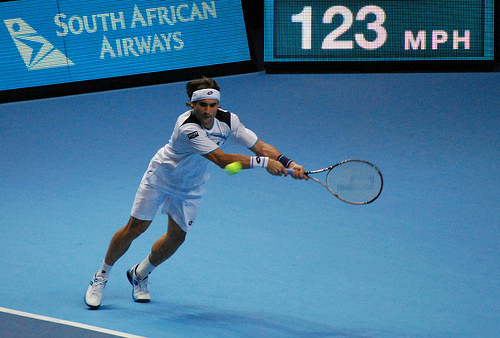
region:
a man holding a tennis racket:
[113, 61, 405, 214]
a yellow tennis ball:
[200, 139, 270, 192]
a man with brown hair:
[177, 67, 244, 127]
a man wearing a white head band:
[160, 55, 250, 147]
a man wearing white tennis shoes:
[78, 74, 250, 315]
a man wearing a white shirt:
[131, 82, 275, 201]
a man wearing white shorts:
[123, 75, 275, 258]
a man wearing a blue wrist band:
[262, 148, 314, 186]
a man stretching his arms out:
[133, 66, 410, 191]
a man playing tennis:
[60, 64, 398, 316]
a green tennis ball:
[226, 162, 241, 174]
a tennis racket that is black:
[326, 163, 386, 204]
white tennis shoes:
[86, 275, 112, 307]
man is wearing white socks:
[129, 261, 171, 271]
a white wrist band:
[248, 157, 270, 167]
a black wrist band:
[280, 150, 290, 163]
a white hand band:
[193, 90, 221, 98]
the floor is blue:
[280, 87, 348, 140]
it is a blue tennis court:
[266, 236, 346, 288]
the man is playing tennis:
[88, 91, 347, 303]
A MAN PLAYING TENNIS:
[80, 70, 386, 310]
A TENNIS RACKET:
[282, 155, 387, 210]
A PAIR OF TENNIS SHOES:
[80, 261, 151, 308]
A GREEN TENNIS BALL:
[220, 151, 247, 176]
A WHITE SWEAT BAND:
[180, 80, 225, 105]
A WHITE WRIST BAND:
[245, 151, 270, 171]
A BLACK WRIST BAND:
[271, 147, 291, 167]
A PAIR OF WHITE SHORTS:
[125, 185, 200, 240]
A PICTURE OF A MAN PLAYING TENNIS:
[76, 66, 386, 306]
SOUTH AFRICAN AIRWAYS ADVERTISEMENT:
[4, 3, 236, 75]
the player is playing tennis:
[36, 62, 465, 327]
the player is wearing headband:
[143, 53, 265, 125]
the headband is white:
[167, 80, 270, 118]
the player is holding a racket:
[130, 73, 416, 228]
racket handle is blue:
[228, 135, 331, 192]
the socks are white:
[70, 240, 185, 297]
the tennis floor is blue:
[34, 117, 121, 242]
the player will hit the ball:
[185, 84, 288, 216]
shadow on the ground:
[122, 292, 256, 332]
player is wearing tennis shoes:
[58, 239, 224, 322]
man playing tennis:
[90, 84, 407, 313]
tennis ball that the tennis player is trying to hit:
[220, 160, 244, 184]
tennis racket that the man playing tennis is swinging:
[291, 159, 439, 231]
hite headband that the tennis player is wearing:
[187, 83, 231, 105]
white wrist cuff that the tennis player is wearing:
[248, 153, 267, 165]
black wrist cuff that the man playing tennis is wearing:
[274, 154, 295, 169]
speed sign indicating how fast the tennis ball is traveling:
[281, 10, 475, 57]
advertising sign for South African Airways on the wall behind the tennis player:
[48, 0, 233, 67]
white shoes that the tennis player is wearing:
[85, 257, 176, 309]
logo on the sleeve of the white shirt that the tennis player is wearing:
[185, 126, 207, 151]